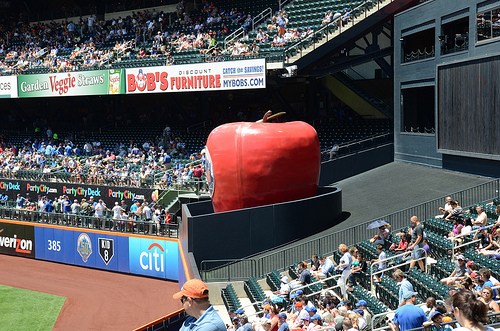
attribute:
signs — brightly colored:
[3, 69, 273, 98]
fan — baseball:
[172, 278, 226, 330]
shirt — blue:
[180, 306, 224, 329]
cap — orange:
[172, 279, 207, 301]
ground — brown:
[73, 271, 173, 328]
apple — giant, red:
[200, 103, 327, 218]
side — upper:
[3, 2, 379, 83]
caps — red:
[259, 301, 302, 309]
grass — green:
[4, 283, 77, 329]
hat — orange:
[170, 277, 215, 304]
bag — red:
[190, 111, 308, 205]